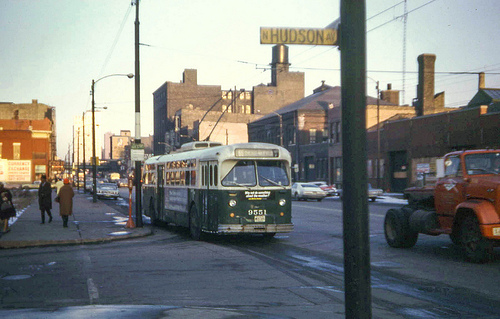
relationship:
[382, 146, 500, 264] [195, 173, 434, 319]
vehicle on road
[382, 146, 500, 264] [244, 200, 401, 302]
vehicle on road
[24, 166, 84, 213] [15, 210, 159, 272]
people on sidewalk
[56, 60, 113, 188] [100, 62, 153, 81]
light on post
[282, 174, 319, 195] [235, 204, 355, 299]
vehicle on road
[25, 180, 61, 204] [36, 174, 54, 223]
coat on people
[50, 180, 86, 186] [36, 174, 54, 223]
hat on people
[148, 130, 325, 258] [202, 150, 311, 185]
windshield on bus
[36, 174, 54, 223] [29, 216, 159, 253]
people on sidewalk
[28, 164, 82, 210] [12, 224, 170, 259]
person on sidewalk